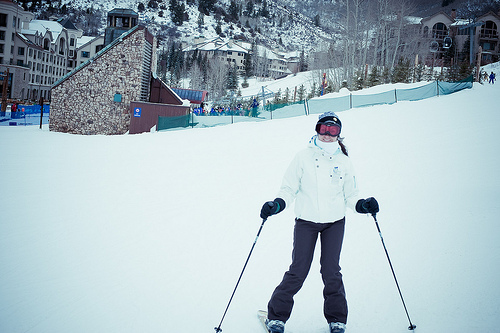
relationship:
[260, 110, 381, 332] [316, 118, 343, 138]
woman wearing goggles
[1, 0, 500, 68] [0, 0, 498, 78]
mountains covered in snow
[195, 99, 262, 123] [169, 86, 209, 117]
people outside of building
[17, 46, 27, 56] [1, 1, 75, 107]
window on edge of building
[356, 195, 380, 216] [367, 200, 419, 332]
hand holding ski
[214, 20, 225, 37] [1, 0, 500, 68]
tree growing on mountains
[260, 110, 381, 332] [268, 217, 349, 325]
woman wearing pants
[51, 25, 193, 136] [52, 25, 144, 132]
building made of stone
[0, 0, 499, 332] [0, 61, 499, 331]
snow on ground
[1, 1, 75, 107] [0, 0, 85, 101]
building has building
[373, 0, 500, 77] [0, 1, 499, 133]
ski lodge in background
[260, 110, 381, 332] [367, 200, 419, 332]
woman has pole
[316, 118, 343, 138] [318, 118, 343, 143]
goggles on womans face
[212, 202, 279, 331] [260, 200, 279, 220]
pole in hand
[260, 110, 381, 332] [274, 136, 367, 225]
woman wearing jacket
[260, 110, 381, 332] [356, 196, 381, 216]
woman wearing glove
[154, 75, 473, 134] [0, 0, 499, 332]
fence in snow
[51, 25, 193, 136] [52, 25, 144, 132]
structure made of stone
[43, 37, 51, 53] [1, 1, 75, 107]
window on front of building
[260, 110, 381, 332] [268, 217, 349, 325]
woman wearing winter pants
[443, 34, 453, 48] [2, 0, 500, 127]
ski lift in air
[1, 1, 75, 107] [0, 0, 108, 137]
hotel in upper left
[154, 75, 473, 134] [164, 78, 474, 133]
fence made of mesh